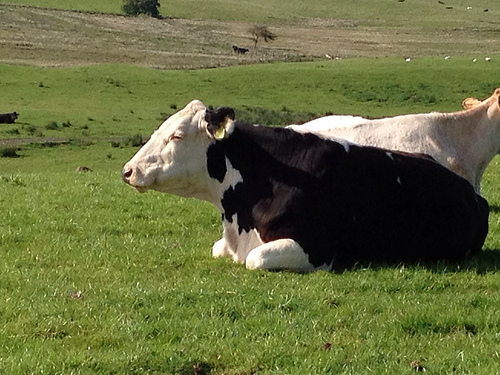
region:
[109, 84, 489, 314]
this is a cow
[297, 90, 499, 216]
this is a cow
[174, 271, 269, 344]
this is grass on the field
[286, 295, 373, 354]
this is grass on the field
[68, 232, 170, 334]
this is grass on the field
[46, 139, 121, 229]
this is grass on the field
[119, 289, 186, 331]
this is grass on the field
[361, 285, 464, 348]
this is grass on the field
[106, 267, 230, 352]
this is grass on the field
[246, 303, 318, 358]
this is grass on the field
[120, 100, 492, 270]
A cow id black and white.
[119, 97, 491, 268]
A cow has an eye that is almost closed.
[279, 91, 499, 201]
A white cow is behind another cow.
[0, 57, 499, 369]
The grass is green.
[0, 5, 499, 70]
Green grass ends and brown grass begins.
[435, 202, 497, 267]
Two shadows are on the grass.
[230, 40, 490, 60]
Six white and one black animal in the distance.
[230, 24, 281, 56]
An animal is by a tree.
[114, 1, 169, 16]
A bush is green.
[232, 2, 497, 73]
Black and white animals are scattered about afield.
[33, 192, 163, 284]
bright green grass growing on ground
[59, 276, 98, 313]
red leaf laying in green grass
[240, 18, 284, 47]
tree growing in the middle of field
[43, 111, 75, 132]
small bushes growing in field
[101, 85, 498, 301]
two cows laying in grassy field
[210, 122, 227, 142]
yellow tag in ear of cow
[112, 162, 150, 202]
black and white nose on cow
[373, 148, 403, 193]
small white spots on side of cow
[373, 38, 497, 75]
sheep grazing in grassy field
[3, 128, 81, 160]
small pond in middle of field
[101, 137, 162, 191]
thwemouth of a cow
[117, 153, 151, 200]
the nose of a cow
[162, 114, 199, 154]
the eye of a cow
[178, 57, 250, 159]
the ear of a cow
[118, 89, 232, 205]
the head of a cow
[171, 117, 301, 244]
the neck of a cow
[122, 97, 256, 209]
the white head of a cow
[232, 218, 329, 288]
the legs of a cow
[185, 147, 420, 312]
the body of a cow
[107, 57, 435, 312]
a cow laying down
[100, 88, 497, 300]
two cows laying on the ground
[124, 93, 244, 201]
white head of cow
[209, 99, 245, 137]
black and white side ear of cow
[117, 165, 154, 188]
small white nose of cow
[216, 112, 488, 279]
black and white body of cow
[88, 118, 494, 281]
large cow laying in the grass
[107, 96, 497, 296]
large cow laying on the field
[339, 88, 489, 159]
brown and white back of cow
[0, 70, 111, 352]
large green grassy field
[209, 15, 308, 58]
small tree in distance